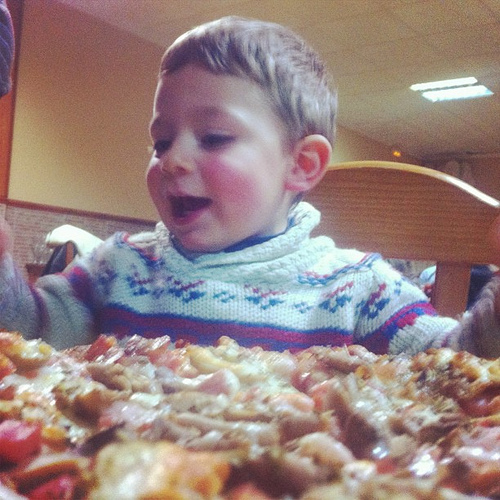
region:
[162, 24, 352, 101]
Blonde hair in the picture.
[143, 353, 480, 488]
A pizza in the photo.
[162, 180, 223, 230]
A smile in the photo.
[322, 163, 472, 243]
wooden chair in the photo.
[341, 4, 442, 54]
A ceiling in the photo.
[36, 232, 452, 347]
A sweater in the photo.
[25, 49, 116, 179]
A wall in the photo.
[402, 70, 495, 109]
Lightings in the room.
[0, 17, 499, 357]
A child in the photo.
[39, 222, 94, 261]
A cloth in the photo.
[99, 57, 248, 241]
the toddler is happy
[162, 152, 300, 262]
the toddler is happy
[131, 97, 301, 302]
the toddler is happy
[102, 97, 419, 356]
the toddler is happy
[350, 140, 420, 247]
the chair is made of wood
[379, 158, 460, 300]
the chair is made of wood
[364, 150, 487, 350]
the chair is made of wood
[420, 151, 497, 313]
the chair is made of wood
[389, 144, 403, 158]
yellow security light lit to show good battery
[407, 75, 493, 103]
bright white incandescent light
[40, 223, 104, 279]
wooden chair with a white jacket and black leather bag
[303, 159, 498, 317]
light wooden highchair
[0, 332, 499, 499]
pizza with man different topping on it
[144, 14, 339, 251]
only baby I have EVER seen that behaves at a restaurant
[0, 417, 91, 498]
pieces of mushrooms and tomatoes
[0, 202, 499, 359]
cute little gray toddler sweater with red and blue on it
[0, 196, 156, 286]
gray and brown laminate brick wall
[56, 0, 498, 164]
off white tiled false ceiling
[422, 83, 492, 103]
a ceiling light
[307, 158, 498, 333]
part of a wooden chair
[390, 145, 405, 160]
an exit sign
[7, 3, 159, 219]
part of a yellow wall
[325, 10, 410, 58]
a white ceiling tile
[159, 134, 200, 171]
the nose of a boy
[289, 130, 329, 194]
the ear of a boy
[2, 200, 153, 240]
a red chair rail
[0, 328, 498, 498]
a large pizza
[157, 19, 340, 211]
a boy's short cut hair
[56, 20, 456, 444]
child sitting in front of pizza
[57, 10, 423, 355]
white child in sweater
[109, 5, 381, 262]
young boy with brown hair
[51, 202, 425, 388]
red, white, and blue knit sweater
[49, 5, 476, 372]
infant in winter sweater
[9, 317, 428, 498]
pizza with colorful toppings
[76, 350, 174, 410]
italian sausage on pizza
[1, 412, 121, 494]
bell peppers on pizza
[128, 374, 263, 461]
melted cheese on pizza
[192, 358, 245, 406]
red onions on pizza